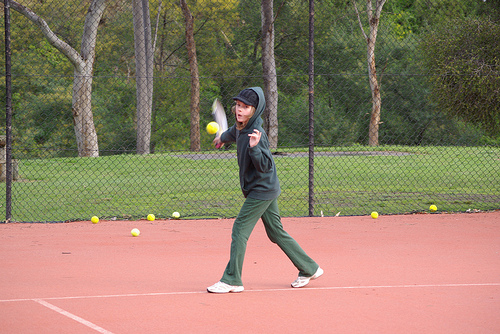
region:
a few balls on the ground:
[60, 200, 182, 241]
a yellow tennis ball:
[196, 116, 222, 143]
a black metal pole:
[294, 45, 329, 218]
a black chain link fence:
[297, 38, 482, 204]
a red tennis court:
[15, 163, 471, 331]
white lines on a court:
[9, 265, 147, 323]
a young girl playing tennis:
[169, 55, 345, 326]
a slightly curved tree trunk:
[61, 17, 120, 159]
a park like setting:
[13, 15, 494, 220]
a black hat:
[224, 82, 276, 118]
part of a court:
[182, 300, 213, 329]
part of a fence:
[341, 165, 396, 243]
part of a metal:
[307, 173, 317, 205]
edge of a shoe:
[196, 279, 220, 298]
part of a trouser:
[285, 252, 305, 277]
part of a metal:
[306, 164, 323, 199]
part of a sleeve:
[244, 145, 266, 158]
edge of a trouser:
[208, 268, 250, 285]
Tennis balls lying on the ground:
[84, 208, 198, 240]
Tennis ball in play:
[202, 111, 229, 146]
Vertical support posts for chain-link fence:
[297, 6, 327, 233]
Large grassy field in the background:
[63, 151, 448, 206]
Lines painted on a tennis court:
[26, 288, 118, 329]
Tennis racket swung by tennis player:
[207, 90, 231, 156]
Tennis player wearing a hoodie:
[205, 74, 328, 302]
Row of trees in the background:
[26, 0, 408, 158]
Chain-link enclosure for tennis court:
[11, 0, 498, 229]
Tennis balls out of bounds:
[87, 205, 195, 245]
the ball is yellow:
[70, 201, 108, 238]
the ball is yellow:
[78, 203, 97, 227]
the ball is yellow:
[81, 186, 130, 253]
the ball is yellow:
[81, 211, 108, 233]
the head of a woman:
[227, 82, 266, 127]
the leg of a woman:
[213, 195, 268, 282]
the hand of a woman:
[243, 122, 267, 148]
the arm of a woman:
[250, 130, 276, 175]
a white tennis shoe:
[286, 261, 326, 292]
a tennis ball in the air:
[200, 118, 225, 137]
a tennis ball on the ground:
[364, 203, 385, 224]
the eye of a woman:
[240, 102, 251, 110]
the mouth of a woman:
[235, 110, 247, 119]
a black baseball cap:
[229, 85, 260, 108]